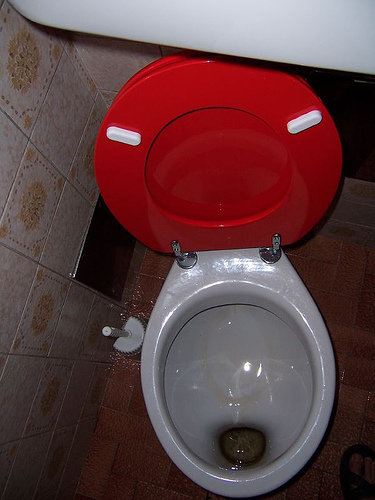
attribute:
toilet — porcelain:
[110, 241, 338, 498]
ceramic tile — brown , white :
[16, 133, 115, 279]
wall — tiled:
[17, 124, 107, 325]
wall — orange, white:
[0, 0, 147, 499]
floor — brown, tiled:
[335, 200, 372, 497]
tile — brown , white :
[5, 112, 51, 190]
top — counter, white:
[18, 9, 373, 75]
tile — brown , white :
[3, 35, 116, 496]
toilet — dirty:
[115, 66, 343, 498]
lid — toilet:
[95, 51, 344, 251]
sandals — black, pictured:
[345, 454, 368, 491]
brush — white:
[98, 322, 149, 359]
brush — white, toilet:
[96, 309, 153, 356]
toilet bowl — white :
[165, 303, 313, 469]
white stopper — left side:
[99, 115, 144, 149]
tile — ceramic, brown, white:
[26, 383, 76, 458]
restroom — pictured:
[11, 6, 362, 497]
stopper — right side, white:
[289, 110, 322, 134]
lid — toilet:
[85, 58, 352, 257]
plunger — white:
[85, 301, 139, 367]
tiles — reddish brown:
[74, 235, 374, 498]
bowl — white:
[137, 248, 335, 498]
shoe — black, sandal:
[316, 441, 373, 492]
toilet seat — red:
[97, 83, 351, 259]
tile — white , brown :
[0, 31, 161, 498]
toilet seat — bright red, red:
[92, 57, 343, 259]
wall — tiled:
[13, 177, 119, 373]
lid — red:
[118, 74, 327, 244]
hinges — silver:
[162, 230, 288, 272]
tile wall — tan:
[2, 3, 137, 498]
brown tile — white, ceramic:
[3, 146, 66, 259]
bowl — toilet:
[144, 277, 329, 489]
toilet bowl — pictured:
[158, 282, 325, 481]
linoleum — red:
[77, 240, 367, 497]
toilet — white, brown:
[84, 42, 352, 498]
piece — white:
[283, 112, 327, 139]